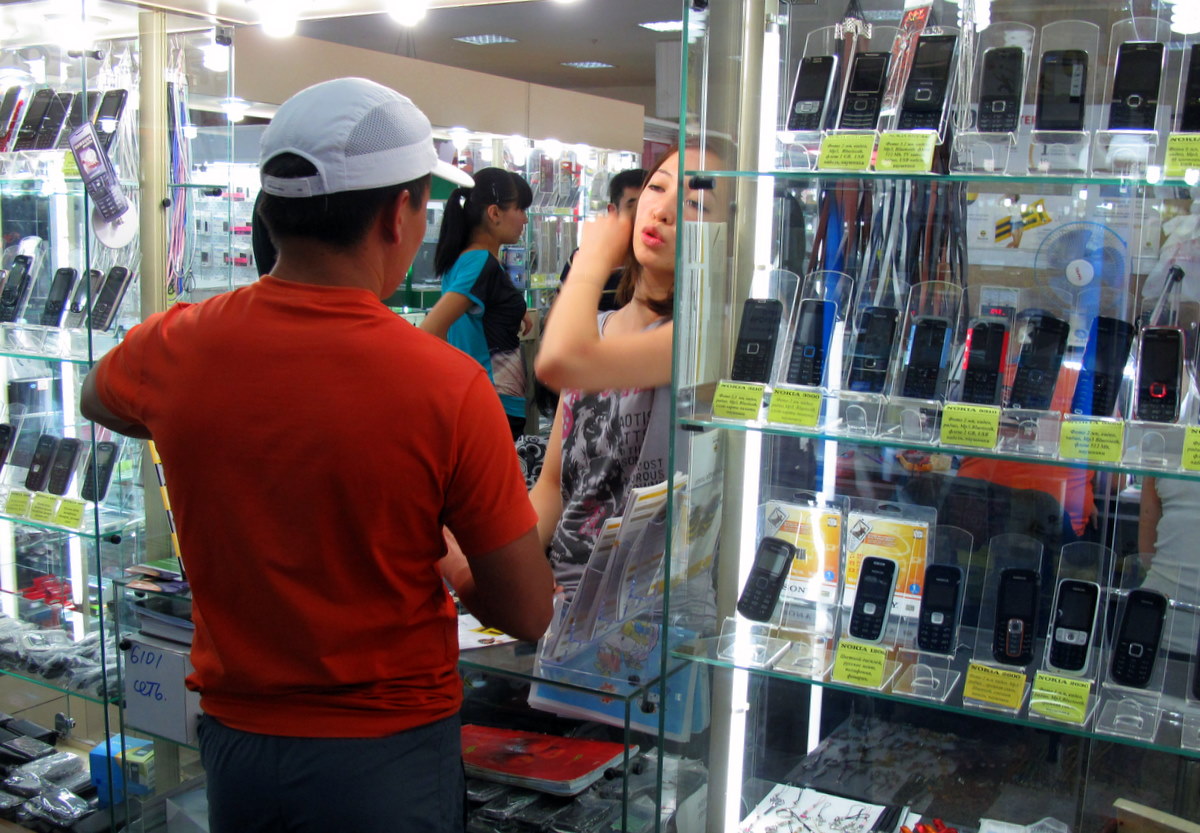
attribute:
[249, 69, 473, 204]
hat — white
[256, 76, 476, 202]
hat — white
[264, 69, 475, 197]
cap — white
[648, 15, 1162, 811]
case — plastic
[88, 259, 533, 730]
shirt — orange, red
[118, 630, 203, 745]
box — white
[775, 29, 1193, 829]
phones — cell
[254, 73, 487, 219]
hat — white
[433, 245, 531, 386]
shirt — blue, black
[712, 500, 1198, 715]
phones — black, cell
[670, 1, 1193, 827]
case — glass, display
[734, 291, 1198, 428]
phones — cell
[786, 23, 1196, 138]
phones — cell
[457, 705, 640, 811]
book — red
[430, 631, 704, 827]
counter — glass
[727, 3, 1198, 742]
rows — three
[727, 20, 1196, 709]
phones — cell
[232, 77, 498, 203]
hat — white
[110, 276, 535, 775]
shirt — red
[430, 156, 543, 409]
woman — walking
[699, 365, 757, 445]
paper — small, yellow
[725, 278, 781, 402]
phone — cell, black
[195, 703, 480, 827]
pants — dark blue